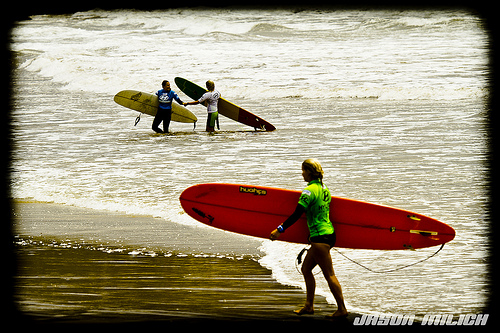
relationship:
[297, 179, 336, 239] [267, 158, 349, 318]
shirt on person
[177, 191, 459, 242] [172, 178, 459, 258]
line down surfboard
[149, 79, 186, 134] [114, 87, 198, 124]
people carrying surfboard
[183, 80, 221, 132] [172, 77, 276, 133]
person carrying surfboard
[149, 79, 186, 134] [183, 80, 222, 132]
people shaking hands with person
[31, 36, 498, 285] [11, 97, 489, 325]
bubbles coming to beach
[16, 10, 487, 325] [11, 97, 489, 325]
water coming to beach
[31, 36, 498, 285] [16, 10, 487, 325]
bubbles on top of water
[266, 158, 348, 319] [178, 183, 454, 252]
girl carrying longboard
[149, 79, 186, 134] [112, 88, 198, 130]
people carrying surfboard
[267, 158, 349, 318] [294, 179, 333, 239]
person wearing green shirt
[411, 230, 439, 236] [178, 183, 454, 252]
fins under longboard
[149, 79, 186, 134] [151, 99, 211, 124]
people wearing shirt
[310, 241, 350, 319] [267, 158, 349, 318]
leg part of person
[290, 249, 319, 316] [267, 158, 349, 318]
leg part of person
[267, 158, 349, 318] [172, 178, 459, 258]
person carrying surfboard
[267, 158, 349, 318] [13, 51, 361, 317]
person walking to shore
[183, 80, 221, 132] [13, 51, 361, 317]
person walking to shore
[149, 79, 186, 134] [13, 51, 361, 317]
people walking to shore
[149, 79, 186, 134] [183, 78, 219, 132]
people shaking hands with surfer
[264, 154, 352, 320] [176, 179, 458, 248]
girl carrying longboard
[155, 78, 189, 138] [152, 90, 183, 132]
man wearing wetsuit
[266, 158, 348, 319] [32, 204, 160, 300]
girl walking to shore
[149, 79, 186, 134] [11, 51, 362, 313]
people enjoying beach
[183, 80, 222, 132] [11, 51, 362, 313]
person enjoying beach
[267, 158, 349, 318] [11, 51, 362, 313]
person enjoying beach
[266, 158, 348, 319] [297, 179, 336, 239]
girl wearing shirt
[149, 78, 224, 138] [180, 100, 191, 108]
people shaking hands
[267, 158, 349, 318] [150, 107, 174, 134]
person wearing black pants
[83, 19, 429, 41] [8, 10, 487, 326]
waves in water